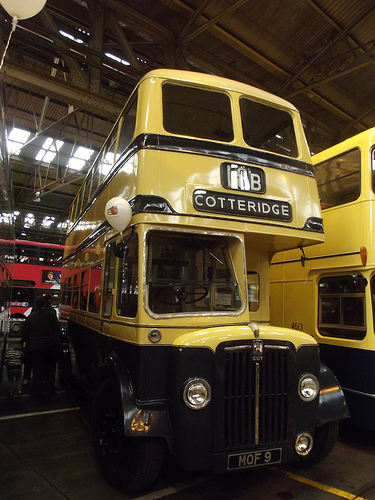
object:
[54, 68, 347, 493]
bus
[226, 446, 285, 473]
license plate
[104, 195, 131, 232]
balloon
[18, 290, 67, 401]
people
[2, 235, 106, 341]
bus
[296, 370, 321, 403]
headlight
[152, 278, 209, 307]
steering wheel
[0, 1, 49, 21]
balloon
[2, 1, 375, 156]
ceiling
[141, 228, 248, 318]
windshield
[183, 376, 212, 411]
headlight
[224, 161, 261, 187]
sign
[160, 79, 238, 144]
window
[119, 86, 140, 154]
window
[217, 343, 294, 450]
grill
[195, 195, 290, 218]
cotteridge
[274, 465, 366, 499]
line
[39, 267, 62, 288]
banner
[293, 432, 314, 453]
light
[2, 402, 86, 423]
line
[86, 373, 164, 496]
wheel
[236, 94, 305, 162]
window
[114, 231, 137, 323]
window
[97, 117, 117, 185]
window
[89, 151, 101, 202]
window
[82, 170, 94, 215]
window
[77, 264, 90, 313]
window